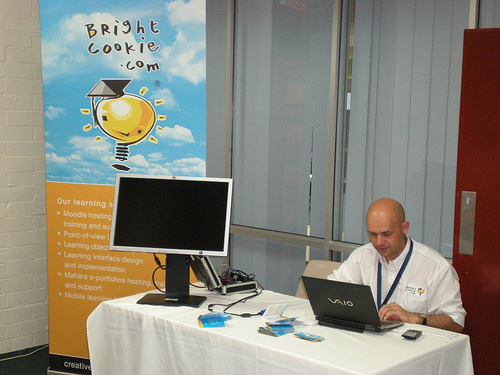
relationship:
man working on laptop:
[330, 196, 464, 333] [302, 274, 401, 332]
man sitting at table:
[330, 196, 464, 333] [77, 276, 470, 373]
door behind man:
[453, 29, 500, 374] [330, 196, 464, 333]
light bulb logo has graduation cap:
[81, 94, 165, 166] [88, 76, 130, 103]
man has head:
[330, 196, 464, 333] [364, 197, 409, 259]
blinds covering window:
[235, 3, 459, 309] [230, 3, 470, 317]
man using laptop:
[330, 196, 464, 333] [302, 274, 401, 332]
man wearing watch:
[330, 196, 464, 333] [417, 312, 428, 325]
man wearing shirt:
[330, 196, 464, 333] [329, 239, 465, 327]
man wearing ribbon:
[330, 196, 464, 333] [374, 237, 413, 315]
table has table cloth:
[77, 276, 470, 373] [86, 273, 472, 373]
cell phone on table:
[403, 326, 422, 340] [77, 276, 470, 373]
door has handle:
[453, 29, 500, 374] [457, 190, 475, 257]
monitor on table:
[111, 172, 234, 309] [77, 276, 470, 373]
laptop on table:
[302, 274, 401, 332] [77, 276, 470, 373]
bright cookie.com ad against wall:
[38, 3, 213, 375] [1, 2, 50, 353]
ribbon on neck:
[374, 237, 413, 315] [374, 236, 411, 263]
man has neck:
[330, 196, 464, 333] [374, 236, 411, 263]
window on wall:
[230, 3, 470, 317] [206, 3, 494, 327]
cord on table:
[148, 255, 217, 297] [77, 276, 470, 373]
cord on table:
[207, 268, 263, 323] [77, 276, 470, 373]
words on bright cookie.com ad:
[51, 195, 168, 306] [38, 3, 213, 375]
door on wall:
[453, 29, 500, 374] [206, 3, 494, 327]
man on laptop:
[330, 196, 464, 333] [302, 274, 401, 332]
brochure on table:
[265, 301, 290, 322] [77, 276, 470, 373]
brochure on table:
[198, 309, 225, 327] [77, 276, 470, 373]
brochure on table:
[263, 323, 293, 332] [77, 276, 470, 373]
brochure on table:
[294, 331, 321, 344] [77, 276, 470, 373]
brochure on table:
[260, 325, 291, 337] [77, 276, 470, 373]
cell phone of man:
[403, 326, 422, 340] [330, 196, 464, 333]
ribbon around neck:
[374, 237, 413, 315] [374, 236, 411, 263]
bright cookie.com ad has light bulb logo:
[38, 3, 213, 375] [81, 94, 165, 166]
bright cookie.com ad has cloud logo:
[38, 3, 213, 375] [43, 15, 156, 82]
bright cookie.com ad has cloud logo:
[38, 3, 213, 375] [152, 119, 194, 146]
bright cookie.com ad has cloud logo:
[38, 3, 213, 375] [47, 135, 118, 172]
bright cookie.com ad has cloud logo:
[38, 3, 213, 375] [164, 5, 206, 86]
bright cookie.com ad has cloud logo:
[38, 3, 213, 375] [126, 154, 151, 171]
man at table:
[330, 196, 464, 333] [77, 276, 470, 373]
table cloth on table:
[86, 273, 472, 373] [77, 276, 470, 373]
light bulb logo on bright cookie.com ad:
[81, 94, 165, 166] [38, 3, 213, 375]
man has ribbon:
[330, 196, 464, 333] [374, 237, 413, 315]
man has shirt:
[330, 196, 464, 333] [329, 239, 465, 327]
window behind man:
[230, 3, 470, 317] [330, 196, 464, 333]